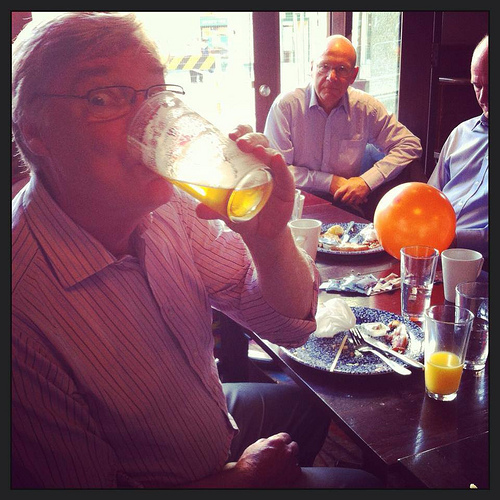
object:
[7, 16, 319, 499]
man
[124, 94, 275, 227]
glass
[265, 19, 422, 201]
person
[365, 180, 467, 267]
ball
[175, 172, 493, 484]
table